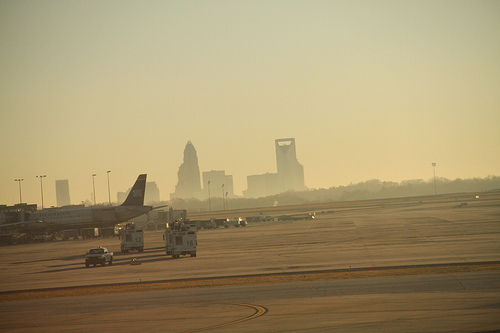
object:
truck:
[164, 224, 199, 259]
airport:
[0, 201, 498, 330]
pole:
[107, 169, 114, 205]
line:
[237, 301, 265, 326]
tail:
[121, 175, 146, 207]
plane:
[1, 173, 168, 225]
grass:
[251, 265, 384, 283]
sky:
[0, 12, 499, 110]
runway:
[253, 209, 490, 255]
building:
[171, 137, 202, 206]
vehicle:
[120, 222, 142, 252]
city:
[156, 95, 484, 208]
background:
[5, 1, 491, 136]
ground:
[286, 280, 499, 331]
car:
[120, 223, 146, 252]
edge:
[195, 141, 205, 190]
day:
[105, 7, 427, 136]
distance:
[34, 74, 449, 232]